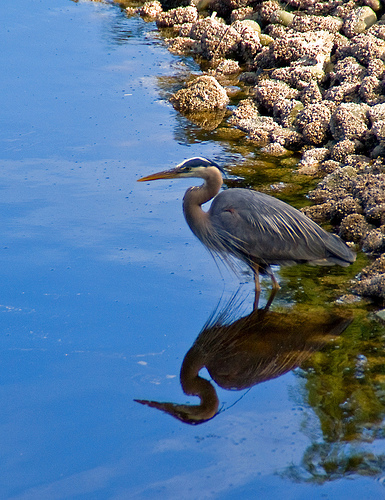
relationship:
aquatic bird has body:
[136, 156, 357, 311] [209, 189, 356, 265]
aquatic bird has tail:
[136, 156, 357, 311] [311, 233, 356, 267]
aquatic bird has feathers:
[136, 156, 357, 311] [201, 221, 261, 290]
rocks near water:
[155, 26, 369, 194] [3, 85, 373, 489]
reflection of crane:
[131, 292, 348, 434] [140, 156, 364, 289]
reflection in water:
[131, 292, 349, 427] [4, 5, 383, 486]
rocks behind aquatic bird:
[144, 0, 383, 301] [136, 156, 357, 311]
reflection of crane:
[131, 292, 349, 427] [131, 141, 381, 323]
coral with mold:
[205, 46, 367, 199] [209, 60, 331, 207]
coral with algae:
[205, 46, 367, 199] [245, 132, 364, 218]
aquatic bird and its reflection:
[136, 156, 357, 311] [126, 294, 364, 435]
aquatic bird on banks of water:
[136, 156, 357, 311] [4, 5, 383, 486]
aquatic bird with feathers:
[136, 156, 357, 311] [201, 182, 362, 277]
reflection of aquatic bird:
[131, 292, 349, 427] [136, 156, 357, 311]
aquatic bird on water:
[136, 156, 357, 311] [4, 5, 383, 486]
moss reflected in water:
[298, 350, 375, 463] [4, 5, 383, 486]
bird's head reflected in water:
[127, 375, 220, 433] [4, 5, 383, 486]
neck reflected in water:
[173, 357, 213, 398] [4, 5, 383, 486]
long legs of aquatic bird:
[243, 254, 289, 331] [136, 156, 357, 311]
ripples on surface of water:
[59, 23, 165, 90] [4, 5, 383, 486]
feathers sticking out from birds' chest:
[199, 227, 270, 293] [159, 204, 276, 287]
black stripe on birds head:
[183, 157, 220, 168] [134, 151, 226, 223]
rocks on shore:
[117, 4, 383, 130] [117, 10, 371, 349]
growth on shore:
[127, 0, 383, 132] [117, 10, 371, 349]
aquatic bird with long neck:
[136, 151, 367, 325] [176, 164, 217, 233]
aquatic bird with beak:
[136, 156, 357, 311] [129, 156, 180, 186]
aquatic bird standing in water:
[136, 156, 357, 311] [4, 5, 383, 486]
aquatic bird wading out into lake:
[136, 156, 357, 311] [5, 2, 378, 496]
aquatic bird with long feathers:
[136, 156, 357, 311] [194, 177, 357, 284]